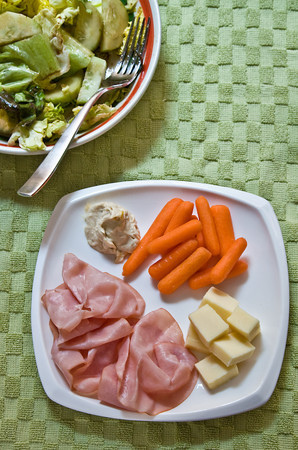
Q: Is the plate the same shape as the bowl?
A: No, the bowl is round and the plate is square.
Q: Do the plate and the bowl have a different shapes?
A: Yes, the plate is round and the bowl is square.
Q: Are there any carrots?
A: Yes, there are carrots.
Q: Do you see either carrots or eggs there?
A: Yes, there are carrots.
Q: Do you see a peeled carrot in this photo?
A: Yes, there are peeled carrots.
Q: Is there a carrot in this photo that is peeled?
A: Yes, there are carrots that are peeled.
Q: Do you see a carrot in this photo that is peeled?
A: Yes, there are carrots that are peeled.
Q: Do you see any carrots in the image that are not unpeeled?
A: Yes, there are peeled carrots.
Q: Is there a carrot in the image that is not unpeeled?
A: Yes, there are peeled carrots.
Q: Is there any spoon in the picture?
A: No, there are no spoons.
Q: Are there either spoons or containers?
A: No, there are no spoons or containers.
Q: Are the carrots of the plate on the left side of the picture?
A: No, the carrots are on the right of the image.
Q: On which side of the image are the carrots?
A: The carrots are on the right of the image.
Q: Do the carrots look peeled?
A: Yes, the carrots are peeled.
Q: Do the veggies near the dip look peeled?
A: Yes, the carrots are peeled.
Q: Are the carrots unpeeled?
A: No, the carrots are peeled.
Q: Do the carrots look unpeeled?
A: No, the carrots are peeled.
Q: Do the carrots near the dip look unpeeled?
A: No, the carrots are peeled.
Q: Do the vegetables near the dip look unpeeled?
A: No, the carrots are peeled.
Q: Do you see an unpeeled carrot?
A: No, there are carrots but they are peeled.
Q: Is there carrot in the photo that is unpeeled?
A: No, there are carrots but they are peeled.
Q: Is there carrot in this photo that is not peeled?
A: No, there are carrots but they are peeled.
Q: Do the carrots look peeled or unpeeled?
A: The carrots are peeled.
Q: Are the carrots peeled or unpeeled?
A: The carrots are peeled.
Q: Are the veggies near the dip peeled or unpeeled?
A: The carrots are peeled.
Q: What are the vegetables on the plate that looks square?
A: The vegetables are carrots.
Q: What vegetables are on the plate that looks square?
A: The vegetables are carrots.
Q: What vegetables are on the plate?
A: The vegetables are carrots.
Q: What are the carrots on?
A: The carrots are on the plate.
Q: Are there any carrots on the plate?
A: Yes, there are carrots on the plate.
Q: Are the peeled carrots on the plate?
A: Yes, the carrots are on the plate.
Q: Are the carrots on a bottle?
A: No, the carrots are on the plate.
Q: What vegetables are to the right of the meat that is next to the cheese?
A: The vegetables are carrots.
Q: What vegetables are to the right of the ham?
A: The vegetables are carrots.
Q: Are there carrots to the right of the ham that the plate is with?
A: Yes, there are carrots to the right of the ham.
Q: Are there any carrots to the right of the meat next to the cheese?
A: Yes, there are carrots to the right of the ham.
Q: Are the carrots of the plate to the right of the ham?
A: Yes, the carrots are to the right of the ham.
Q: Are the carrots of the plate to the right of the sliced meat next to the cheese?
A: Yes, the carrots are to the right of the ham.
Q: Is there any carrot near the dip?
A: Yes, there are carrots near the dip.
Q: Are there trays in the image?
A: No, there are no trays.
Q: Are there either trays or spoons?
A: No, there are no trays or spoons.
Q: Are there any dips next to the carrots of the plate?
A: Yes, there is a dip next to the carrots.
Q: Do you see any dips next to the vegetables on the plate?
A: Yes, there is a dip next to the carrots.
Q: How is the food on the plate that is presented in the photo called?
A: The food is a dip.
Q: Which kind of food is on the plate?
A: The food is a dip.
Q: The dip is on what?
A: The dip is on the plate.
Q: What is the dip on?
A: The dip is on the plate.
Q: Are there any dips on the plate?
A: Yes, there is a dip on the plate.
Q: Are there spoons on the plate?
A: No, there is a dip on the plate.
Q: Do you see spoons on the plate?
A: No, there is a dip on the plate.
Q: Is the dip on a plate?
A: Yes, the dip is on a plate.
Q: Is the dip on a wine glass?
A: No, the dip is on a plate.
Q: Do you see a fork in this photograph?
A: Yes, there is a fork.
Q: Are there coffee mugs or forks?
A: Yes, there is a fork.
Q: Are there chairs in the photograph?
A: No, there are no chairs.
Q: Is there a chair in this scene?
A: No, there are no chairs.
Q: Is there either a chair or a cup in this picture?
A: No, there are no chairs or cups.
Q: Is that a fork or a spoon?
A: That is a fork.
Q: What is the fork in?
A: The fork is in the bowl.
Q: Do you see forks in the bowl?
A: Yes, there is a fork in the bowl.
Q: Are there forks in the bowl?
A: Yes, there is a fork in the bowl.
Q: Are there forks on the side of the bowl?
A: Yes, there is a fork on the side of the bowl.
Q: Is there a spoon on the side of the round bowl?
A: No, there is a fork on the side of the bowl.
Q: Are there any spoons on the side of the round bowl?
A: No, there is a fork on the side of the bowl.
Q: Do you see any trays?
A: No, there are no trays.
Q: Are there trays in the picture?
A: No, there are no trays.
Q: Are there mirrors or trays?
A: No, there are no trays or mirrors.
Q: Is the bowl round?
A: Yes, the bowl is round.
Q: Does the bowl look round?
A: Yes, the bowl is round.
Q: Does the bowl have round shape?
A: Yes, the bowl is round.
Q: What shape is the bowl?
A: The bowl is round.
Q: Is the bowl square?
A: No, the bowl is round.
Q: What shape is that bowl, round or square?
A: The bowl is round.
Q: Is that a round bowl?
A: Yes, that is a round bowl.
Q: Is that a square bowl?
A: No, that is a round bowl.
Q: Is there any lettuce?
A: Yes, there is lettuce.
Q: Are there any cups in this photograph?
A: No, there are no cups.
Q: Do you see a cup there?
A: No, there are no cups.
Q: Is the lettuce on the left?
A: Yes, the lettuce is on the left of the image.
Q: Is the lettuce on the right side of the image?
A: No, the lettuce is on the left of the image.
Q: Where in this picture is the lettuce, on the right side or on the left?
A: The lettuce is on the left of the image.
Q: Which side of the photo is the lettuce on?
A: The lettuce is on the left of the image.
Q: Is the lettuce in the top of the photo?
A: Yes, the lettuce is in the top of the image.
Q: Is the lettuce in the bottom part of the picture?
A: No, the lettuce is in the top of the image.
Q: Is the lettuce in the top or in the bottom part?
A: The lettuce is in the top of the image.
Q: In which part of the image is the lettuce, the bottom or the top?
A: The lettuce is in the top of the image.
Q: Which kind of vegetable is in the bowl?
A: The vegetable is lettuce.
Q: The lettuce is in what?
A: The lettuce is in the bowl.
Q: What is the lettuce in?
A: The lettuce is in the bowl.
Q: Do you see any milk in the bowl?
A: No, there is lettuce in the bowl.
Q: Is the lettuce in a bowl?
A: Yes, the lettuce is in a bowl.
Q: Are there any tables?
A: Yes, there is a table.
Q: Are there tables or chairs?
A: Yes, there is a table.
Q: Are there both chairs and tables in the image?
A: No, there is a table but no chairs.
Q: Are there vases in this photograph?
A: No, there are no vases.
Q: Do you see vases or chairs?
A: No, there are no vases or chairs.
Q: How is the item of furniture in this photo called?
A: The piece of furniture is a table.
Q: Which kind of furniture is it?
A: The piece of furniture is a table.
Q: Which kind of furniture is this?
A: This is a table.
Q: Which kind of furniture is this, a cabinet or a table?
A: This is a table.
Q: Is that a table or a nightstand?
A: That is a table.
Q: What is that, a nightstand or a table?
A: That is a table.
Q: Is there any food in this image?
A: Yes, there is food.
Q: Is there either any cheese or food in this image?
A: Yes, there is food.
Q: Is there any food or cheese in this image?
A: Yes, there is food.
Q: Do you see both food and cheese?
A: Yes, there are both food and cheese.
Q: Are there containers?
A: No, there are no containers.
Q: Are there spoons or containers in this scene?
A: No, there are no containers or spoons.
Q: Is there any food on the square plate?
A: Yes, there is food on the plate.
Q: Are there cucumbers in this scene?
A: Yes, there is a cucumber.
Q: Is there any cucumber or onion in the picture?
A: Yes, there is a cucumber.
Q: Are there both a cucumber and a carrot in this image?
A: Yes, there are both a cucumber and a carrot.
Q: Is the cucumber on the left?
A: Yes, the cucumber is on the left of the image.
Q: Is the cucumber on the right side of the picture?
A: No, the cucumber is on the left of the image.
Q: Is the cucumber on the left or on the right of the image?
A: The cucumber is on the left of the image.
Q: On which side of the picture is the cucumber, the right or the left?
A: The cucumber is on the left of the image.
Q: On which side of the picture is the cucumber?
A: The cucumber is on the left of the image.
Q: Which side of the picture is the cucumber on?
A: The cucumber is on the left of the image.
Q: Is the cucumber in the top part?
A: Yes, the cucumber is in the top of the image.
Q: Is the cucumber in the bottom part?
A: No, the cucumber is in the top of the image.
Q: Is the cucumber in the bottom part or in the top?
A: The cucumber is in the top of the image.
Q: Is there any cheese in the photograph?
A: Yes, there is cheese.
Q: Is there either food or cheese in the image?
A: Yes, there is cheese.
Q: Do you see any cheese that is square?
A: Yes, there is cheese that is square.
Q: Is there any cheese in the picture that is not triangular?
A: Yes, there is square cheese.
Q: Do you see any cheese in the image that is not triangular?
A: Yes, there is square cheese.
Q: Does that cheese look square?
A: Yes, the cheese is square.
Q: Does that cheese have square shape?
A: Yes, the cheese is square.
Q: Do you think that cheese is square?
A: Yes, the cheese is square.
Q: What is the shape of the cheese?
A: The cheese is square.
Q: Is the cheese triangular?
A: No, the cheese is square.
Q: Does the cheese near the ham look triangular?
A: No, the cheese is square.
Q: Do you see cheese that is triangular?
A: No, there is cheese but it is square.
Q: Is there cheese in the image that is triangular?
A: No, there is cheese but it is square.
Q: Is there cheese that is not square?
A: No, there is cheese but it is square.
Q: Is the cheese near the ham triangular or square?
A: The cheese is square.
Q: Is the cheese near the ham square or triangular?
A: The cheese is square.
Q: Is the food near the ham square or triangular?
A: The cheese is square.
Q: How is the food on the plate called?
A: The food is cheese.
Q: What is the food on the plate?
A: The food is cheese.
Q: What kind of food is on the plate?
A: The food is cheese.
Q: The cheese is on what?
A: The cheese is on the plate.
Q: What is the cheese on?
A: The cheese is on the plate.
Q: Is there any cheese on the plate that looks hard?
A: Yes, there is cheese on the plate.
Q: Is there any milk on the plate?
A: No, there is cheese on the plate.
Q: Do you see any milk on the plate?
A: No, there is cheese on the plate.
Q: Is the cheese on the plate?
A: Yes, the cheese is on the plate.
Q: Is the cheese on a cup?
A: No, the cheese is on the plate.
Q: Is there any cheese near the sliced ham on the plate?
A: Yes, there is cheese near the ham.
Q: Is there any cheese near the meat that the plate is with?
A: Yes, there is cheese near the ham.